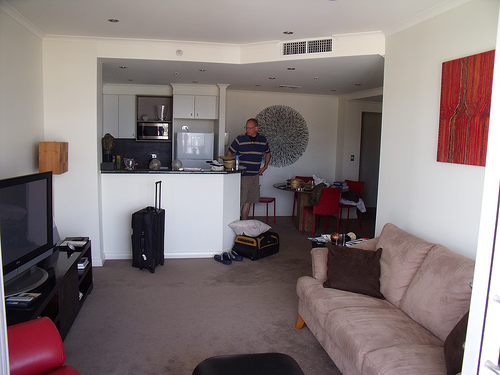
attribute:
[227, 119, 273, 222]
man — standing, standing up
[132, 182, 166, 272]
suitcase — rolling, tall, upright, black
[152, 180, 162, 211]
handle — extended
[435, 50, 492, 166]
artwork — bright, red, abstract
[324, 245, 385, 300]
pillow — brown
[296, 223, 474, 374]
couch — tan, suede, light brown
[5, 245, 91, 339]
entertainment center — shiny, black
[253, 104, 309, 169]
decoration — round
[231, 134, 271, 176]
shirt — striped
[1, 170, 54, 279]
television — flat, gray, black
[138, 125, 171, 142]
microwave — small, silver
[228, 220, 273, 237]
pillow — white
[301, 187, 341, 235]
chair — plastic, red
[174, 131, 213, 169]
refrigerator — white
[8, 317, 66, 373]
arm — leather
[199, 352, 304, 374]
ottoman — black